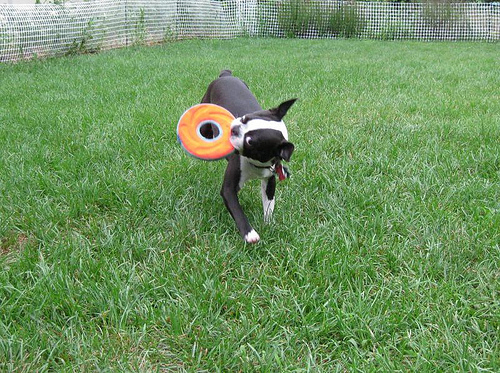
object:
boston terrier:
[199, 67, 298, 242]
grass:
[2, 32, 497, 371]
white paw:
[242, 227, 260, 244]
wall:
[325, 115, 340, 169]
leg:
[219, 155, 260, 243]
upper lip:
[199, 68, 298, 245]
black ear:
[270, 97, 299, 119]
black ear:
[277, 140, 295, 162]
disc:
[176, 103, 238, 161]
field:
[24, 26, 496, 326]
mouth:
[228, 116, 245, 154]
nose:
[231, 125, 241, 137]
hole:
[199, 122, 220, 140]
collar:
[248, 160, 291, 181]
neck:
[237, 157, 291, 178]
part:
[340, 245, 402, 307]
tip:
[243, 227, 260, 243]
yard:
[353, 129, 449, 265]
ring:
[176, 103, 238, 162]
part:
[182, 128, 190, 136]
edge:
[334, 332, 348, 359]